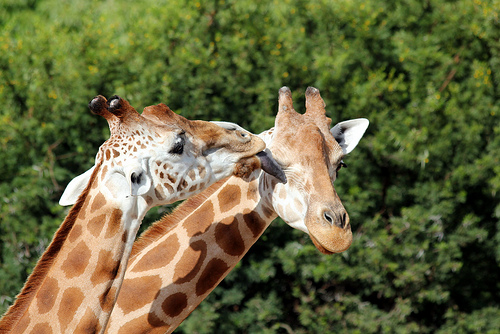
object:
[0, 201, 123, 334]
coat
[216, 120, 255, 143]
nose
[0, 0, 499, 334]
trees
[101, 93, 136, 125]
horns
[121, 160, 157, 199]
ear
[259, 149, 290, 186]
tongue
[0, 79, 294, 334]
giraffe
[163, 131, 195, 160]
eyes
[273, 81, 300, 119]
horns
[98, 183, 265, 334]
neck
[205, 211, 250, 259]
spots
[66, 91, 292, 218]
head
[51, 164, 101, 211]
ears